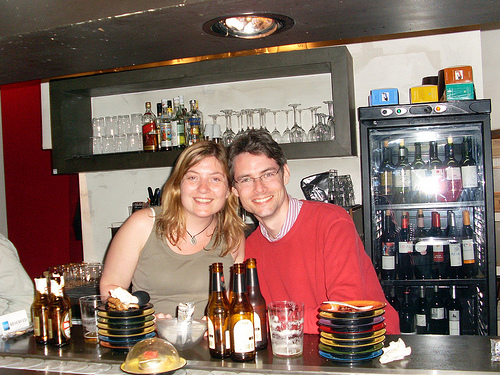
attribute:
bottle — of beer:
[33, 270, 52, 347]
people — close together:
[85, 109, 440, 353]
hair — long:
[154, 139, 245, 257]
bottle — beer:
[193, 249, 224, 353]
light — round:
[213, 12, 282, 43]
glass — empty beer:
[266, 299, 306, 357]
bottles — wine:
[368, 140, 485, 193]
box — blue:
[367, 84, 401, 106]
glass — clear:
[266, 301, 302, 355]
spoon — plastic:
[322, 295, 380, 311]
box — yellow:
[408, 84, 439, 104]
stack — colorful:
[314, 300, 386, 364]